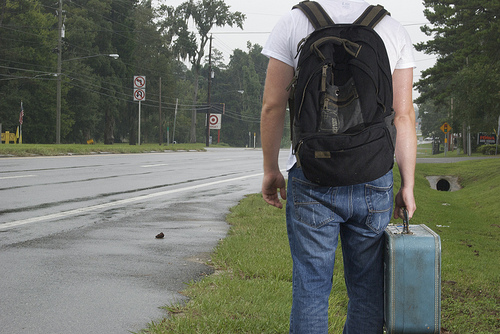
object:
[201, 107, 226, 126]
sign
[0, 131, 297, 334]
road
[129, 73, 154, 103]
road signs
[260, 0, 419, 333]
person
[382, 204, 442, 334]
case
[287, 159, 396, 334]
jeans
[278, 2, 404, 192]
backpack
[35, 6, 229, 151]
light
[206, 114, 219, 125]
logo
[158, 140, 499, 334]
grass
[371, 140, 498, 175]
driveway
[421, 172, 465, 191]
pipe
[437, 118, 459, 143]
yellow sign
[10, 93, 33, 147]
flag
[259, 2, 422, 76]
shirt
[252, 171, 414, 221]
hands